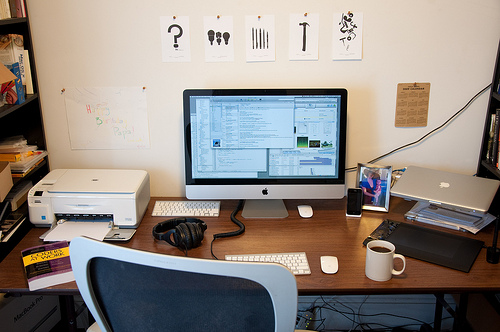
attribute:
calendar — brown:
[376, 77, 441, 141]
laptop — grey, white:
[391, 163, 498, 213]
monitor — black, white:
[181, 84, 352, 222]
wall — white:
[33, 2, 497, 202]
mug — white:
[363, 235, 406, 283]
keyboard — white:
[152, 196, 219, 217]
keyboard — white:
[224, 250, 309, 276]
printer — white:
[26, 167, 148, 240]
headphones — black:
[138, 210, 220, 250]